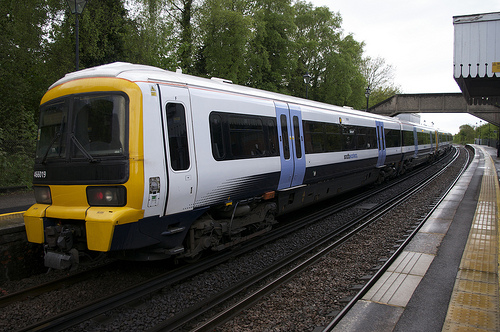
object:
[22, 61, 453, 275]
train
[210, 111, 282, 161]
windows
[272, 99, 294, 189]
doors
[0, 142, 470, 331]
tracks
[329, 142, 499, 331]
platform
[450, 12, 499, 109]
awning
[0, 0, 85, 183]
trees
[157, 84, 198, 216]
door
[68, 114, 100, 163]
wipers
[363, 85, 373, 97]
light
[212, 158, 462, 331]
gravel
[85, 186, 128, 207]
headlights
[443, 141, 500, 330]
line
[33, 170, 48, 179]
number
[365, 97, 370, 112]
pole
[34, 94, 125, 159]
windshield